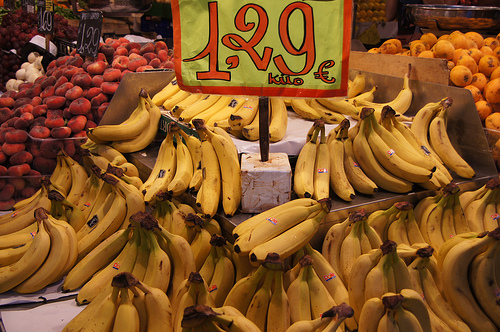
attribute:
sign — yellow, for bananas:
[169, 1, 351, 96]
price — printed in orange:
[183, 1, 338, 83]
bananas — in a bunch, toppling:
[229, 193, 335, 272]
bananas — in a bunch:
[291, 115, 332, 208]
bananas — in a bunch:
[187, 116, 245, 229]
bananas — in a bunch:
[81, 84, 164, 157]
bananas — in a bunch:
[137, 119, 208, 210]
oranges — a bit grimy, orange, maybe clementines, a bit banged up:
[364, 28, 499, 153]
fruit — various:
[1, 1, 499, 329]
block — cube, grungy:
[238, 149, 293, 216]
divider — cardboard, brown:
[344, 46, 499, 175]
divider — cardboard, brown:
[96, 62, 174, 126]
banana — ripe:
[416, 192, 452, 259]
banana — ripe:
[429, 116, 475, 183]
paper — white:
[155, 94, 430, 159]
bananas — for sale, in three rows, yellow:
[0, 60, 499, 330]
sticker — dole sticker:
[315, 166, 326, 176]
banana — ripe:
[315, 122, 332, 211]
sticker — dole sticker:
[322, 270, 337, 286]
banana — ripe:
[142, 122, 178, 205]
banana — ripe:
[390, 115, 453, 182]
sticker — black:
[84, 214, 100, 230]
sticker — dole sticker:
[207, 282, 218, 297]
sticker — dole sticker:
[267, 216, 278, 226]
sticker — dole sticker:
[387, 148, 397, 157]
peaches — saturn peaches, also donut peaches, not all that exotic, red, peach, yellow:
[0, 32, 174, 214]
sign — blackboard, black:
[78, 9, 104, 59]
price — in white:
[76, 23, 100, 57]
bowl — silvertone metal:
[402, 4, 499, 27]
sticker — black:
[228, 98, 238, 110]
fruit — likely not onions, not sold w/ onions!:
[0, 48, 47, 100]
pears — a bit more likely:
[3, 51, 47, 94]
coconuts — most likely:
[0, 51, 46, 101]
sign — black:
[35, 9, 55, 37]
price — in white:
[36, 8, 52, 35]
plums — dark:
[0, 46, 26, 95]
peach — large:
[125, 49, 149, 70]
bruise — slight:
[129, 57, 142, 63]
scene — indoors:
[1, 1, 499, 331]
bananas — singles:
[348, 60, 417, 117]